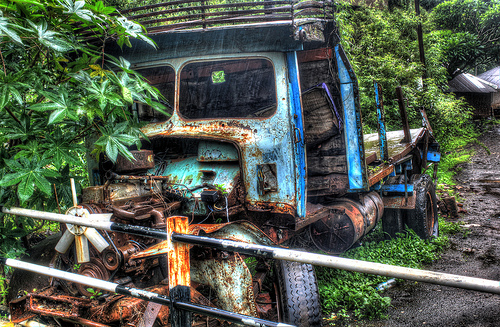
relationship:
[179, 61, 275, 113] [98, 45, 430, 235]
window of truck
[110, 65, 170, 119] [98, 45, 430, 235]
window of truck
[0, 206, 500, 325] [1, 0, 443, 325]
bar on truck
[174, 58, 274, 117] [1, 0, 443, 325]
windshield on truck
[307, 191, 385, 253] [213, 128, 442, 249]
barrel under truck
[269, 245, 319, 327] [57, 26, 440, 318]
tire on truck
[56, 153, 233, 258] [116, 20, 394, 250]
engine on truck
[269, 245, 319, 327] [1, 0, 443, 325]
tire of a truck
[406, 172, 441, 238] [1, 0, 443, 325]
wheel of a truck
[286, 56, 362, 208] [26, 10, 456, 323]
door of a truck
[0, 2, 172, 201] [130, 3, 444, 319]
bushes near a truck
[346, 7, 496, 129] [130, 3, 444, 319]
bushes near a truck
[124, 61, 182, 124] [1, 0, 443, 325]
windshield of truck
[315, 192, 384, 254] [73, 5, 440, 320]
gas tank on rusty truck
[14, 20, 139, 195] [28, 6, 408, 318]
tree beside truck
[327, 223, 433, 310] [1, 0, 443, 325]
weeds under truck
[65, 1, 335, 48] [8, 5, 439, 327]
fence on top of rusty truck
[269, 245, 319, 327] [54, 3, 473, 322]
tire turned under truck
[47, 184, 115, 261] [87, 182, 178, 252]
fan on engine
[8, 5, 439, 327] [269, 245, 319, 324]
rusty truck has tire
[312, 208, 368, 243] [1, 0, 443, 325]
exhaust pipe of truck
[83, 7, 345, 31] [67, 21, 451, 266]
railing of truck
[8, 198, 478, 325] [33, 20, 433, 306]
bar in front of truck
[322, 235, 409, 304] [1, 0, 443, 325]
grass under truck